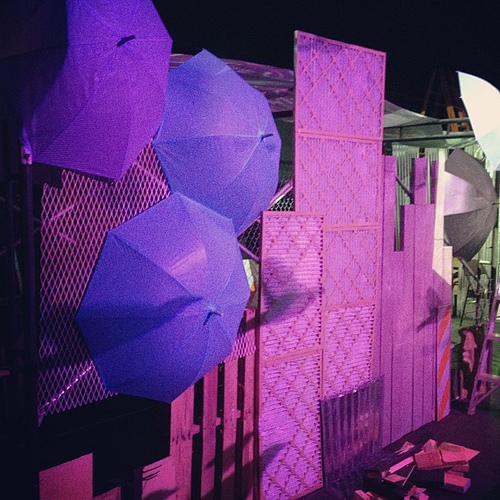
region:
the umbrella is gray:
[440, 142, 495, 260]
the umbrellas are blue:
[128, 53, 313, 384]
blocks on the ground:
[319, 418, 486, 499]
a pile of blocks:
[346, 433, 488, 498]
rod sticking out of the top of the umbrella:
[207, 301, 227, 320]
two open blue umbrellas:
[66, 51, 291, 403]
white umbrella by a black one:
[430, 55, 499, 263]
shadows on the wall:
[191, 423, 288, 499]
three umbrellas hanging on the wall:
[11, 0, 288, 417]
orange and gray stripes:
[431, 310, 459, 418]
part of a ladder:
[466, 283, 499, 412]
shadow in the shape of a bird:
[412, 286, 455, 336]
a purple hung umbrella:
[1, 0, 179, 186]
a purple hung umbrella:
[69, 186, 258, 426]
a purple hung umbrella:
[148, 27, 278, 244]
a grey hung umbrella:
[431, 135, 492, 255]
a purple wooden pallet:
[151, 299, 266, 496]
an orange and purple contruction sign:
[433, 294, 458, 424]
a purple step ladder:
[457, 241, 498, 412]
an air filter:
[251, 194, 325, 366]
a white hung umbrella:
[448, 51, 498, 179]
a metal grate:
[52, 85, 184, 417]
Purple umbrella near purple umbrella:
[74, 191, 252, 404]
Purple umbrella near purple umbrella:
[150, 43, 280, 233]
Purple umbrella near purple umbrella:
[20, 0, 170, 176]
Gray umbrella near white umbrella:
[435, 147, 498, 260]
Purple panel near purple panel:
[293, 29, 378, 390]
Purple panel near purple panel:
[257, 210, 325, 498]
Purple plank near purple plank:
[390, 248, 403, 440]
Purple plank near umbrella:
[242, 308, 259, 499]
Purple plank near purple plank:
[203, 360, 213, 496]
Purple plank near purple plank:
[221, 357, 235, 499]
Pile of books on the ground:
[351, 434, 471, 498]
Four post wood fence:
[162, 303, 263, 498]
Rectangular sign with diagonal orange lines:
[430, 299, 456, 421]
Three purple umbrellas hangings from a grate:
[6, 0, 282, 400]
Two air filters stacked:
[257, 208, 325, 499]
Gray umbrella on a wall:
[438, 143, 498, 261]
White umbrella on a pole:
[453, 66, 498, 165]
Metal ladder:
[466, 269, 498, 422]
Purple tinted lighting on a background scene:
[8, 18, 498, 498]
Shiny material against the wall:
[317, 374, 385, 486]